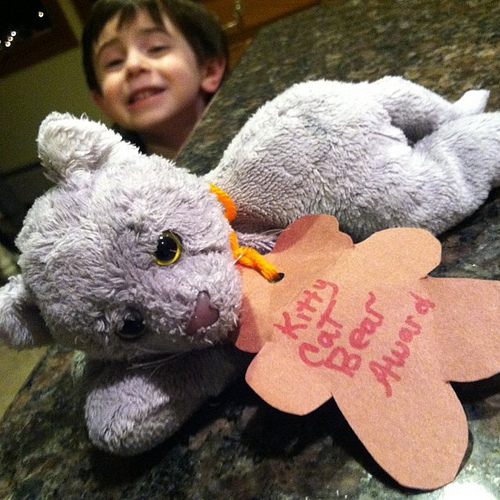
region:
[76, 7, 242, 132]
Small child in the background.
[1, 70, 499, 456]
Gray cat on the countertop.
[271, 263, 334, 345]
Kitty written on the paper.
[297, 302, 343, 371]
Cat written on the paper.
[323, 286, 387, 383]
Bear written on the paper.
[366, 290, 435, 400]
Award writte on the paper.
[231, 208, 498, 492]
Brown bear construction paper shape.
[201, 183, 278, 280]
Orange yarn on kitty.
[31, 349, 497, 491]
Shadow of the cat on countertop.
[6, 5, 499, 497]
Countertop where stuffed animal is sitting.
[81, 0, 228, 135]
the face of a young boy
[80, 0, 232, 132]
a little boy looking at the teddy bear on the countertop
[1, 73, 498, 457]
a white stuffed animal on top of a granite tabletop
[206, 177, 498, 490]
a kitty cat bear award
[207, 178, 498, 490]
a paper kitty cat bear award around the stuffed animal's neck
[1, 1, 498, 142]
a young boy in the kitchen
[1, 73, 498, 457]
a kitty cat bear toy for the little boy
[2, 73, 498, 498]
an award given to the young child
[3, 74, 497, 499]
a white kitty bear on top of the counter in the kitchen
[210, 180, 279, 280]
a yellow yarn tied to the award and the bear's neck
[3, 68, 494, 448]
a stuff toy kitty on the counter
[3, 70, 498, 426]
a purple stuff toy kitty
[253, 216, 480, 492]
a tag of the stuff toy kitty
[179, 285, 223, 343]
a nose of the stuff toy kitty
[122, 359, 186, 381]
whiskers of the kitty stuff toy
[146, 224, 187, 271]
an eye of the kitty stuff toy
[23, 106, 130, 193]
the ear of the kitty stuff toy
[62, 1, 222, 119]
a boy in the background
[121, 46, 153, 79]
a nose of the boy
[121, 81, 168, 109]
a smile of the boy in the background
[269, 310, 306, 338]
a letter on a note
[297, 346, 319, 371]
a letter on a note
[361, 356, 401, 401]
a letter on a note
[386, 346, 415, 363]
a letter on a note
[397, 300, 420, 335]
a letter on a note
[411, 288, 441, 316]
a letter on a note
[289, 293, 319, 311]
a letter on a note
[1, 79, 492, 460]
this is a teddy bear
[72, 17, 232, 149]
the head of a girl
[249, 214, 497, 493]
a tag on a teddy bear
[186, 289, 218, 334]
stuffed animal has a pink nose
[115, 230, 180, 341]
stuffed animal has green eyes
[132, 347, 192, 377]
the animals whiskers are white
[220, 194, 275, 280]
yellow yarn around stuffed animal's neck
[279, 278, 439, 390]
brown tag with red letters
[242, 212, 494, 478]
brown paper tag on a yellow string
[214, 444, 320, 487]
counter top is grey marble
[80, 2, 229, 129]
boy smiling in the background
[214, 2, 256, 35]
shiny handle behind boy's head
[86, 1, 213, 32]
boy has straight brown hair